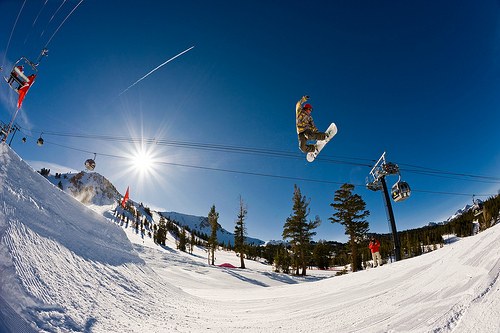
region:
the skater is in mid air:
[296, 95, 339, 160]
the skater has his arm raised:
[292, 95, 319, 119]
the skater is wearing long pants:
[298, 127, 324, 149]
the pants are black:
[293, 125, 326, 152]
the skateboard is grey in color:
[300, 121, 341, 163]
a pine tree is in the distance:
[283, 183, 322, 277]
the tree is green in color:
[283, 185, 314, 270]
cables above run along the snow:
[11, 115, 493, 202]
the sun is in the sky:
[113, 129, 174, 186]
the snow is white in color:
[2, 136, 497, 330]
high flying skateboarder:
[295, 91, 339, 163]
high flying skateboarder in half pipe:
[1, 93, 499, 332]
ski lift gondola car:
[390, 167, 410, 200]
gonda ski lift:
[0, 120, 496, 260]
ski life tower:
[367, 151, 404, 264]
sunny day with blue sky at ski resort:
[0, 5, 497, 322]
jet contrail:
[124, 46, 193, 90]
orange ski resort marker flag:
[115, 186, 129, 223]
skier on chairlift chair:
[5, 48, 47, 94]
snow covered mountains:
[33, 162, 498, 244]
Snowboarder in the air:
[281, 81, 361, 204]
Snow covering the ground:
[20, 273, 63, 327]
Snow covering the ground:
[80, 287, 149, 327]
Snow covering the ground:
[139, 288, 188, 330]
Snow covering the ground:
[191, 292, 247, 324]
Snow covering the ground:
[261, 283, 322, 327]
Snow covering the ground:
[328, 279, 385, 317]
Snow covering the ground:
[394, 268, 484, 328]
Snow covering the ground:
[332, 259, 402, 296]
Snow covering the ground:
[170, 264, 355, 321]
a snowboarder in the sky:
[290, 87, 343, 162]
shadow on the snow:
[37, 203, 140, 267]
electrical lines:
[156, 133, 191, 170]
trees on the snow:
[276, 188, 324, 270]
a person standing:
[363, 233, 398, 265]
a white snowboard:
[313, 121, 338, 145]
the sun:
[128, 130, 163, 180]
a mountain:
[76, 179, 103, 193]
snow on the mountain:
[76, 174, 106, 201]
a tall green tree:
[284, 188, 316, 262]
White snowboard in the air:
[304, 118, 346, 169]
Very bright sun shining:
[94, 110, 203, 200]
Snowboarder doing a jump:
[276, 85, 351, 170]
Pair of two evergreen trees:
[274, 181, 374, 273]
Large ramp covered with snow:
[11, 171, 207, 331]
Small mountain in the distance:
[46, 160, 147, 228]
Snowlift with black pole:
[360, 153, 429, 261]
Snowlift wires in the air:
[384, 142, 490, 214]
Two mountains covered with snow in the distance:
[51, 148, 271, 274]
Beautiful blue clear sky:
[2, 1, 499, 205]